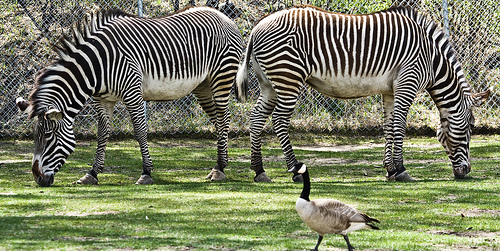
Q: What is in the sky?
A: Clouds.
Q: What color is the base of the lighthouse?
A: White.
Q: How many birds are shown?
A: One.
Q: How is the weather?
A: Sunny.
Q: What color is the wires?
A: Black.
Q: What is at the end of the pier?
A: A building.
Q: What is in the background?
A: Fence.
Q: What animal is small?
A: Bird.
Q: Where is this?
A: Enclosure.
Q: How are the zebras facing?
A: Opposite.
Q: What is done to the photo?
A: Filtered.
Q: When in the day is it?
A: Afternoon.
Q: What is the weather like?
A: Fair.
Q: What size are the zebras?
A: Adult.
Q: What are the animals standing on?
A: Grass.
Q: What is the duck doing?
A: Wallking near the zebras.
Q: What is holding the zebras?
A: Fence.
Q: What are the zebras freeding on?
A: Grass.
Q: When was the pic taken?
A: During the day.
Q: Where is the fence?
A: Near the animals.